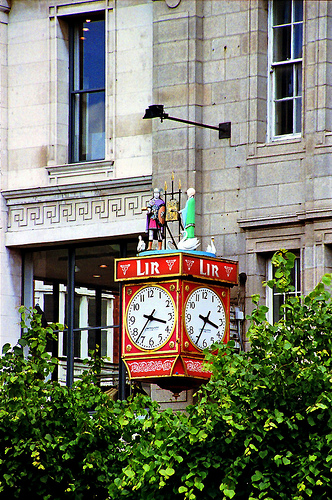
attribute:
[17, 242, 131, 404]
window frame — black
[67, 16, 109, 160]
window frame — black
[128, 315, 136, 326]
number — black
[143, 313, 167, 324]
hand — black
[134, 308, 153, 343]
hand — black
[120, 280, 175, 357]
clock — lir clock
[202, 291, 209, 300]
number — black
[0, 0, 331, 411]
building — modern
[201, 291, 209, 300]
number — black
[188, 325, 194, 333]
number — black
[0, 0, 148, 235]
building — stone, Cream colored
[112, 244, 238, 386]
face — white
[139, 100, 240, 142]
lamp — modern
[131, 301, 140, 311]
number — black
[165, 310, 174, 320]
number — black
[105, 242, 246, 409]
clock — bit off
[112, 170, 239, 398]
clock — decorative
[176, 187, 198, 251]
statue — Mini-statue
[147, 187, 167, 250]
statue — Mini-statue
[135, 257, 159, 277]
lir — in all caps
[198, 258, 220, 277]
lir — in all caps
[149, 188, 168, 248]
statue — represention the story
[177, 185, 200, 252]
statue — represention the story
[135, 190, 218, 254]
art — mechanized art , ghastly, gaudy, rendition of Irish myth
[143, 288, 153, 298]
number — black